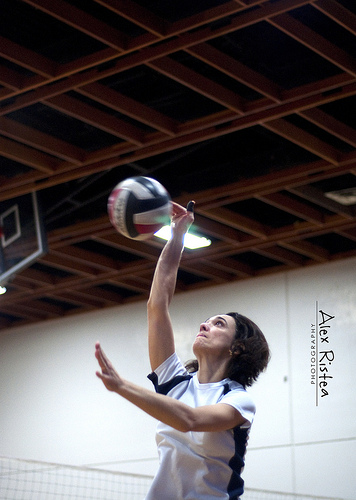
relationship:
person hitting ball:
[82, 170, 296, 499] [98, 168, 180, 247]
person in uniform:
[82, 170, 296, 499] [124, 353, 262, 499]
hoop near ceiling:
[1, 177, 69, 279] [1, 0, 355, 303]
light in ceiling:
[138, 206, 227, 269] [1, 0, 355, 303]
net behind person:
[1, 447, 224, 498] [82, 170, 296, 499]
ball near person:
[98, 168, 180, 247] [82, 170, 296, 499]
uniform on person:
[124, 353, 262, 499] [82, 170, 296, 499]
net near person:
[1, 447, 224, 498] [82, 170, 296, 499]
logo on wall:
[293, 295, 339, 429] [2, 310, 354, 496]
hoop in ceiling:
[1, 177, 69, 279] [1, 0, 355, 303]